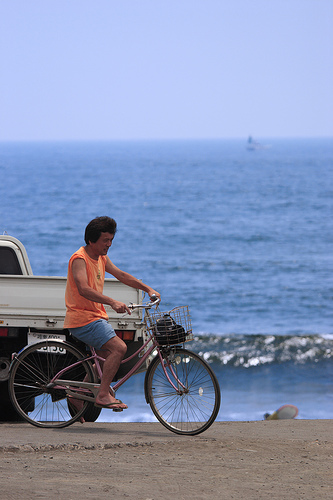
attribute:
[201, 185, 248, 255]
water — large, blue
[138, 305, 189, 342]
basket — wrie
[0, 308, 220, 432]
bike — purple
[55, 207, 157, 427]
man — riding, looking, having, out, enjoying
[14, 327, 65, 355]
license plate — white, black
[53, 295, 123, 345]
truck — hite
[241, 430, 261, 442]
sand — dark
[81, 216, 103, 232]
hair — black, dark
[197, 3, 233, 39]
sky — blue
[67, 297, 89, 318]
shirt — orange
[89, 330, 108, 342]
shorts — blue, short